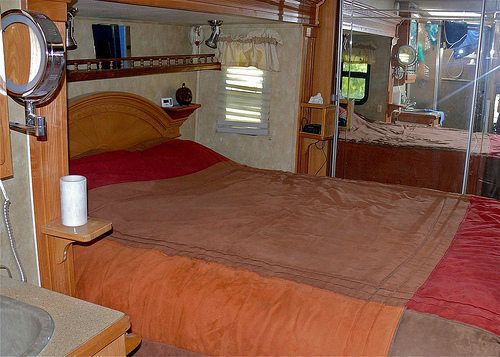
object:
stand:
[40, 216, 114, 266]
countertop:
[1, 273, 131, 357]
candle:
[58, 173, 90, 228]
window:
[215, 62, 273, 138]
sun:
[225, 65, 262, 126]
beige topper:
[187, 25, 284, 72]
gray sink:
[1, 293, 59, 357]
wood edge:
[1, 272, 134, 357]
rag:
[423, 108, 446, 127]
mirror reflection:
[391, 37, 420, 88]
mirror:
[336, 0, 500, 200]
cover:
[69, 137, 500, 356]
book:
[90, 22, 123, 70]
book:
[118, 23, 128, 69]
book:
[125, 25, 132, 69]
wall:
[195, 23, 306, 173]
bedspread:
[69, 137, 500, 357]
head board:
[69, 90, 190, 160]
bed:
[335, 102, 500, 199]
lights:
[204, 19, 225, 49]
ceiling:
[68, 0, 305, 25]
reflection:
[400, 93, 445, 127]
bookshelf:
[66, 52, 223, 84]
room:
[0, 0, 500, 357]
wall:
[337, 0, 500, 134]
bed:
[60, 89, 500, 357]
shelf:
[38, 213, 114, 244]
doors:
[339, 26, 388, 124]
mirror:
[0, 8, 70, 143]